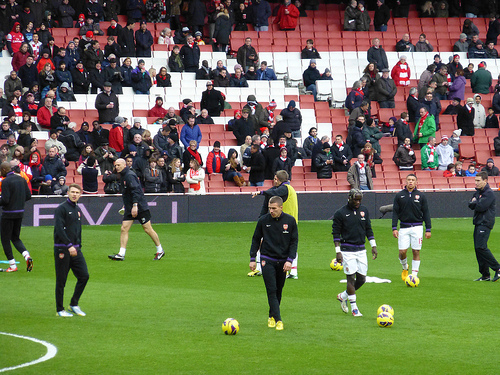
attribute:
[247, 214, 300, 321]
warm ups — black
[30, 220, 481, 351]
grass — short, green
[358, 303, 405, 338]
soccer ball — yellow, blue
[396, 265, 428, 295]
soccer ball — yellow, blue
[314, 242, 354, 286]
soccer ball — yellow, blue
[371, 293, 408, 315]
soccer ball — yellow, blue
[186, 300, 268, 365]
soccer ball — yellow, blue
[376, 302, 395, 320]
ball — soccer ball, yellow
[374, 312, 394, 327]
ball — soccer ball, yellow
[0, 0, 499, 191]
seats — orange, white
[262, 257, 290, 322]
pants — black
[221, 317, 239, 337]
ball — yellow, black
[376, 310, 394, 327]
ball — yellow, black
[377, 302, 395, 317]
ball — yellow, black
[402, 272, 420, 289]
ball — yellow, black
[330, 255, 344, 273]
ball — yellow, black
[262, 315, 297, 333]
shoes — yellow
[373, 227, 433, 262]
shorts — white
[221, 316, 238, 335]
soccer ball — black, yellow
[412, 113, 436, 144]
jacket — green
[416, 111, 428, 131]
shirt — red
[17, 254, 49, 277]
cleats — orange, black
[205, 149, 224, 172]
jacket — red, black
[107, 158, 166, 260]
man — bald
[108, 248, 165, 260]
shoes — Nike brand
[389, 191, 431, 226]
jacket — black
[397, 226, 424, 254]
shorts — white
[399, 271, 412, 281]
shoes — yellow